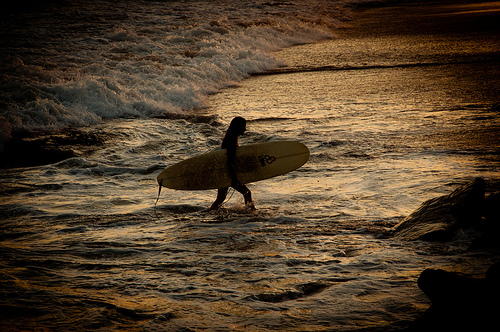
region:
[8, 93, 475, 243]
a person has finished surfing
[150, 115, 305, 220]
a surfer is carrying a surf board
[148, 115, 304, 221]
the surfer is tethered to a surfboard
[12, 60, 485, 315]
waves are crashing on the beach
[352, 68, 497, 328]
rocks are on the beach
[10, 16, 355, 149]
the cream of the waves is white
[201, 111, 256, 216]
the surfer is walking in the water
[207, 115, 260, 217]
the surfboard is under the surfer's arm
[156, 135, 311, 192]
the surfboard has a lengthwise stringer down the middle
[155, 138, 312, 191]
the surfboard is pale yellow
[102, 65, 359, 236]
surfer carrying board horizontally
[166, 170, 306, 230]
knees below surfboard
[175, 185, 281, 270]
water level below knees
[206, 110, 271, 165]
woman leaning slightly forward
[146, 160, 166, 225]
strap hanging from end of board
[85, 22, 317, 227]
waves to the side of surfer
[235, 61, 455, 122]
calm water ahead of wave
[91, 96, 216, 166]
swirl of water behind surfer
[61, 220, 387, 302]
coppery hue to water surface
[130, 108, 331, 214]
front of board higher than back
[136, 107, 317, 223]
Person holding a surfboard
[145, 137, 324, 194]
White longboard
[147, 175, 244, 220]
Leash of the surfboard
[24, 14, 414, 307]
Person walking in the ocean water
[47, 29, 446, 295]
Person exiting the ocean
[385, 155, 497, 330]
Rocks along the shoreline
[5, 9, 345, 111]
Wave breaking on the shore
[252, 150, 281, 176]
Surf logo on the bottom of the board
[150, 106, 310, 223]
Person holding a surfboard with their right arm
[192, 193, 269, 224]
Person's feet hidden in the water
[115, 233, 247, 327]
the water is wet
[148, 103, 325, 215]
the girl is in the water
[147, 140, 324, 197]
the board is long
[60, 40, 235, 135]
the waves has bubbles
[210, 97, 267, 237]
the person is wet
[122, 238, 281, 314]
the ocean is bigh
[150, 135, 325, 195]
the board is yellow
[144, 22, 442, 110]
the water isn't clear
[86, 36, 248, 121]
the waves are rough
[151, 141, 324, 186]
the board has a design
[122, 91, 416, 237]
a surfer carrying his board into the sea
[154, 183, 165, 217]
a black rip cord on the board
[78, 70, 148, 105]
white foam on top of wave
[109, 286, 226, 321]
evening light reflecting on the surface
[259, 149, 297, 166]
a black logo on a yellow surfboard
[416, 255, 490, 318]
a black rock on the edge of the water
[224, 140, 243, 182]
an arm holding a surfboard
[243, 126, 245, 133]
a nose on the profile on a face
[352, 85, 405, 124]
soft ripples on the dark sea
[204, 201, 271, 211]
legs splashing water into the air